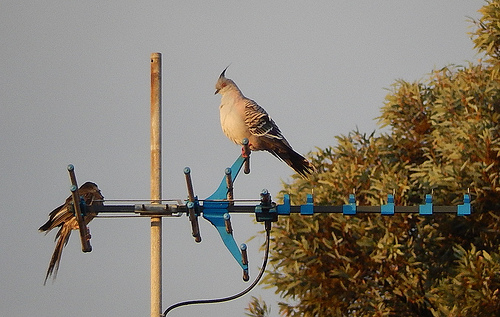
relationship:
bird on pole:
[215, 66, 319, 183] [150, 50, 163, 316]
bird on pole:
[39, 181, 104, 284] [150, 50, 163, 316]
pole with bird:
[150, 50, 163, 316] [215, 66, 319, 183]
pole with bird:
[150, 50, 163, 316] [39, 181, 104, 284]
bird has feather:
[215, 66, 319, 183] [220, 63, 230, 77]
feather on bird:
[220, 63, 230, 77] [215, 66, 319, 183]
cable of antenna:
[163, 222, 272, 316] [69, 138, 474, 282]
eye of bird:
[222, 82, 226, 87] [215, 66, 319, 183]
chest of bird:
[221, 95, 240, 129] [215, 66, 319, 183]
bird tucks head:
[39, 181, 104, 284] [83, 182, 98, 192]